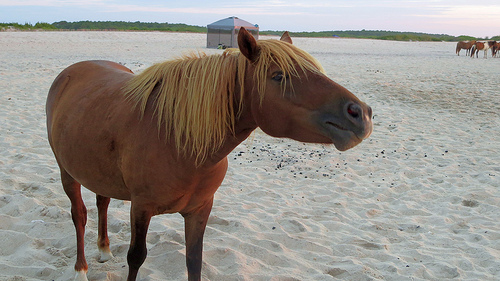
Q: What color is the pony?
A: Brown.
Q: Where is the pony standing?
A: On the sand.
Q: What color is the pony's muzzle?
A: Gray.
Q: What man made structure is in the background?
A: A tent.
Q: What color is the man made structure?
A: Gray.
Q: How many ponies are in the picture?
A: Four.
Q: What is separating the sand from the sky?
A: Trees.